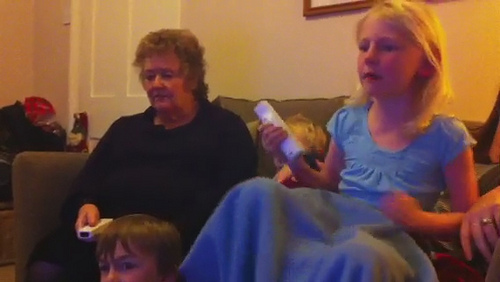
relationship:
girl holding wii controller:
[177, 0, 478, 282] [247, 95, 323, 171]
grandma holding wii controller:
[24, 29, 258, 282] [68, 200, 117, 238]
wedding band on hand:
[475, 215, 488, 229] [446, 169, 497, 257]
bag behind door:
[25, 92, 60, 147] [42, 0, 169, 163]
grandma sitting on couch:
[24, 29, 258, 282] [6, 69, 495, 280]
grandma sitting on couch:
[79, 21, 274, 255] [23, 82, 498, 278]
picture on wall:
[302, 0, 372, 15] [225, 0, 476, 110]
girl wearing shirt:
[264, 3, 461, 280] [321, 98, 476, 240]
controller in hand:
[250, 96, 320, 166] [253, 115, 305, 161]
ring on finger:
[479, 210, 492, 228] [476, 210, 497, 253]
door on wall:
[57, 0, 190, 150] [6, 0, 497, 147]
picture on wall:
[294, 0, 405, 21] [6, 0, 497, 147]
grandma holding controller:
[24, 29, 258, 282] [78, 222, 102, 237]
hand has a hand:
[461, 186, 500, 261] [461, 186, 500, 261]